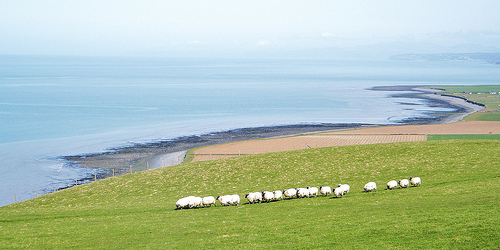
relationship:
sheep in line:
[173, 173, 425, 210] [172, 173, 425, 212]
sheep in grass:
[173, 173, 425, 210] [3, 86, 493, 246]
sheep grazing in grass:
[173, 173, 425, 210] [3, 86, 493, 246]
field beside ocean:
[3, 87, 499, 245] [6, 50, 497, 203]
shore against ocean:
[191, 120, 498, 165] [6, 50, 497, 203]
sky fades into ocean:
[3, 0, 495, 68] [6, 50, 497, 203]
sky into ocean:
[3, 0, 495, 68] [6, 50, 497, 203]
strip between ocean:
[192, 121, 499, 163] [6, 50, 497, 203]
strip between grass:
[192, 121, 499, 163] [3, 86, 493, 246]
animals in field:
[174, 175, 427, 213] [3, 87, 499, 245]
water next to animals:
[5, 50, 499, 204] [174, 175, 427, 213]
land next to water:
[5, 90, 499, 243] [5, 50, 499, 204]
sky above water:
[3, 0, 495, 68] [5, 50, 499, 204]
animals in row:
[174, 175, 427, 213] [172, 173, 425, 212]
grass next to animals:
[3, 86, 493, 246] [174, 175, 427, 213]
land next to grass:
[184, 119, 499, 168] [3, 86, 493, 246]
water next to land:
[5, 50, 499, 204] [5, 90, 499, 243]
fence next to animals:
[9, 154, 182, 205] [174, 175, 427, 213]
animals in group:
[174, 175, 427, 213] [172, 178, 424, 210]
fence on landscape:
[9, 154, 182, 205] [4, 87, 500, 244]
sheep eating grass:
[364, 181, 378, 191] [3, 86, 493, 246]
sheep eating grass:
[385, 176, 401, 192] [3, 86, 493, 246]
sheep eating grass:
[398, 175, 412, 192] [3, 86, 493, 246]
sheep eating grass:
[412, 176, 423, 188] [3, 86, 493, 246]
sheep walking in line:
[173, 173, 425, 210] [172, 173, 425, 212]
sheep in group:
[173, 173, 425, 210] [172, 183, 350, 209]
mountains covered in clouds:
[393, 31, 499, 79] [390, 31, 500, 84]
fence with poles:
[9, 154, 182, 205] [9, 154, 185, 206]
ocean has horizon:
[6, 50, 497, 203] [2, 54, 500, 62]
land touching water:
[184, 119, 499, 168] [5, 50, 499, 204]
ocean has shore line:
[6, 50, 497, 203] [6, 84, 487, 216]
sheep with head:
[385, 176, 401, 192] [386, 183, 394, 192]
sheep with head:
[398, 175, 412, 192] [398, 180, 403, 185]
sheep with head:
[412, 176, 423, 188] [409, 176, 416, 181]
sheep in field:
[173, 173, 425, 210] [3, 87, 499, 245]